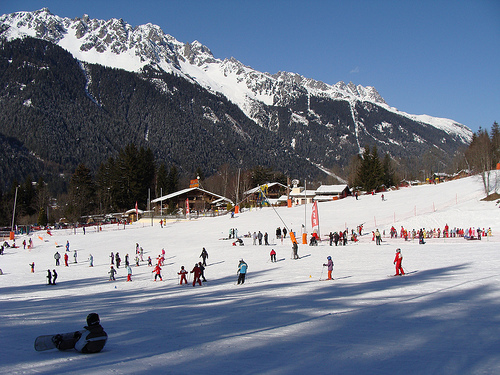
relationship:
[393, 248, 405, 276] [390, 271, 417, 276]
person on snowboard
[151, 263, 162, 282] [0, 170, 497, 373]
people in snow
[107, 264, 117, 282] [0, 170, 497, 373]
person in snow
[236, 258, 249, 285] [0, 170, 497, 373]
people in snow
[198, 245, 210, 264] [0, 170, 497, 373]
person in snow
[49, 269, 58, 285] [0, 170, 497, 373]
person in snow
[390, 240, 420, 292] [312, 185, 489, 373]
person on ski slope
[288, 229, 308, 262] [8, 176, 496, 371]
person on ski slope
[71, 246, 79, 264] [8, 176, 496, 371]
person on ski slope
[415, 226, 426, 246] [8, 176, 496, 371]
standing person standing on ski slope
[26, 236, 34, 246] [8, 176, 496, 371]
standing person standing on ski slope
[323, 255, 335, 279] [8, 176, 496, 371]
people standing on ski slope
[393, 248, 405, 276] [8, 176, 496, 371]
person standing on ski slope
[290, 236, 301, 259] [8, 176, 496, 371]
standing person standing on ski slope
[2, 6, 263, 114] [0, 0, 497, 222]
snow lying on top of hill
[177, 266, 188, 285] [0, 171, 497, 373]
people skiing on hill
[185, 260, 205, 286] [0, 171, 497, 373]
person skiing on hill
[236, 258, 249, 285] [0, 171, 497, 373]
people skiing on hill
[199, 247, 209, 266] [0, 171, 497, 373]
person skiing on hill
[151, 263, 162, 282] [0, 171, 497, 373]
people skiing on hill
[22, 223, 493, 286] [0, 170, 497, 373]
group skiing on snow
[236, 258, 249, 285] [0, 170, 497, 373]
people skiing on snow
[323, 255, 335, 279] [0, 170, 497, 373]
people skiing on snow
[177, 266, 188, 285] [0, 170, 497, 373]
people skiing on snow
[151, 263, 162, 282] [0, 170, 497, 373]
people skiing on snow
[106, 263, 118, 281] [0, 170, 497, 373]
person skiing on snow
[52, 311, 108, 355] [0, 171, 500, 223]
man sitting on hill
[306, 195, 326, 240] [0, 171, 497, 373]
flag standing on hill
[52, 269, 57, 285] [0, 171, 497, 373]
people skiing on hill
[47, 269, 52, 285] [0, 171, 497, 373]
person skiing on hill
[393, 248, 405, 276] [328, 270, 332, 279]
person wearing red pants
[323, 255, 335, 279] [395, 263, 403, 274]
people wearing red pants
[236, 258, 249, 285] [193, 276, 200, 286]
people wearing red pants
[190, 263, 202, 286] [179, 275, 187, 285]
people wearing red pants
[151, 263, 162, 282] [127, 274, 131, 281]
people wearing red pants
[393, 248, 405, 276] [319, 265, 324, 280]
person holding ski pole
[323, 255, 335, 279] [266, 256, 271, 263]
people holding ski pole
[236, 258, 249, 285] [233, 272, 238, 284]
people holding ski pole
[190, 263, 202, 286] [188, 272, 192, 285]
people holding ski pole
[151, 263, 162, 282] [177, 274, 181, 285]
people holding ski pole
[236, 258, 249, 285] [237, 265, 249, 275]
people wearing jacket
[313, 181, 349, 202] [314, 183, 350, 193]
building with roof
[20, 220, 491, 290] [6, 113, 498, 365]
group in snow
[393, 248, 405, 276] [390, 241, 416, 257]
person wearing a hat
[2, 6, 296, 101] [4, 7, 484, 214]
snow on mountain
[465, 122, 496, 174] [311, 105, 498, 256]
trees on hill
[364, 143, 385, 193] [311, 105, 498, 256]
tree on hill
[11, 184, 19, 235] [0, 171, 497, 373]
pole on hill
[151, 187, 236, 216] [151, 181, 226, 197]
brown cabin covered with snow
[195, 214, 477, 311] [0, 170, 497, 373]
people in snow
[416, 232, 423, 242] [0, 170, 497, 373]
people in snow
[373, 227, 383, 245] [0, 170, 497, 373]
people in snow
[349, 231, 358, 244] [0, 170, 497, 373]
people in snow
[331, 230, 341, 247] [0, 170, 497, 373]
people in snow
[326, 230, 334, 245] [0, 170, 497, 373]
people in snow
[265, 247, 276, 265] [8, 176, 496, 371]
person standing on ski slope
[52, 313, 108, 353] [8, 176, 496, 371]
man standing on ski slope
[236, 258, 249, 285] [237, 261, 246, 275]
people wearing jacket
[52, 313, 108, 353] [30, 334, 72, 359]
man on snowboard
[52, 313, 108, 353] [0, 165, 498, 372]
man sitting on ground